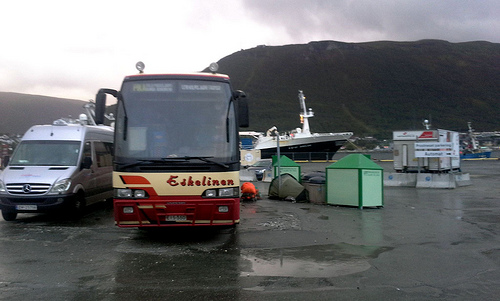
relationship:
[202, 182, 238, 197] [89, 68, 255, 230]
headlight on bus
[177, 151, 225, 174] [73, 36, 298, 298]
wiper on bus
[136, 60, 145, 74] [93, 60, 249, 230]
light on top of bus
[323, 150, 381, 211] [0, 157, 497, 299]
tent on parking lot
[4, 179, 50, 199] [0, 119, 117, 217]
grille on van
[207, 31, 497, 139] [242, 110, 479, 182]
mountain behind boats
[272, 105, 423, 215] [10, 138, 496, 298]
tent on parking lot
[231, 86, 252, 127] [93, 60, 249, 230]
mirror on bus